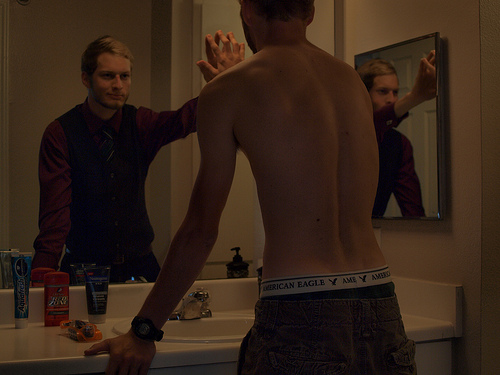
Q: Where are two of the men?
A: In the mirror.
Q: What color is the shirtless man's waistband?
A: White.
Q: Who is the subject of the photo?
A: The man.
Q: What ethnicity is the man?
A: Caucasian.